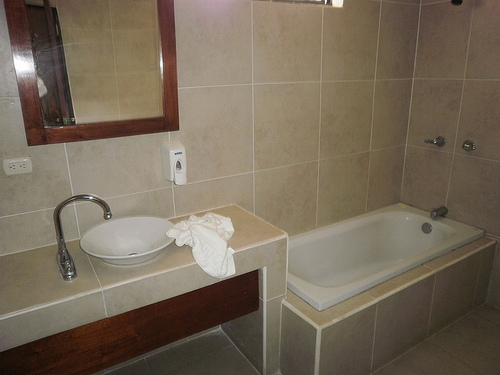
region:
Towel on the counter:
[165, 206, 235, 300]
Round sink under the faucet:
[77, 202, 194, 284]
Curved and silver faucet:
[42, 170, 129, 301]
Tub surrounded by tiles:
[327, 310, 378, 372]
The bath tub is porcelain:
[274, 188, 499, 337]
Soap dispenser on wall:
[160, 144, 200, 191]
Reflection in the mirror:
[27, 16, 174, 126]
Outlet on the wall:
[0, 148, 42, 195]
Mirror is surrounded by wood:
[145, 40, 210, 142]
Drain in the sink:
[122, 245, 139, 259]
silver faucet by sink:
[50, 186, 111, 278]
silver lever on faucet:
[61, 262, 73, 279]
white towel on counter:
[172, 205, 236, 265]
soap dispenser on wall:
[158, 142, 192, 187]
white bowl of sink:
[87, 205, 177, 265]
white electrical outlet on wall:
[0, 157, 32, 179]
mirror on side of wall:
[41, 0, 165, 117]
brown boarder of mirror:
[160, 0, 188, 131]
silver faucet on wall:
[426, 203, 454, 216]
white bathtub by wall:
[275, 206, 457, 303]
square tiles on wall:
[0, 5, 492, 242]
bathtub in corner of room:
[262, 194, 492, 371]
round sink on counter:
[78, 213, 175, 266]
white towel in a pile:
[169, 210, 237, 278]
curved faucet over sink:
[52, 192, 112, 281]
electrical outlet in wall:
[0, 155, 32, 176]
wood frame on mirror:
[7, 0, 179, 148]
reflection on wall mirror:
[28, 2, 167, 127]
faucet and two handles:
[421, 133, 475, 220]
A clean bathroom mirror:
[5, 13, 215, 124]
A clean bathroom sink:
[76, 212, 173, 253]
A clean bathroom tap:
[31, 180, 104, 301]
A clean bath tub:
[285, 199, 479, 289]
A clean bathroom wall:
[197, 76, 324, 160]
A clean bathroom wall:
[315, 77, 407, 180]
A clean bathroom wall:
[183, 12, 303, 67]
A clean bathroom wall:
[347, 9, 448, 66]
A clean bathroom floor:
[436, 326, 493, 371]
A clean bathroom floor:
[179, 348, 249, 373]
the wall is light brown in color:
[263, 79, 368, 182]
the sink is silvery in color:
[41, 190, 110, 256]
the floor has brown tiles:
[407, 300, 474, 370]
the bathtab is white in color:
[308, 199, 476, 257]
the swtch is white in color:
[163, 138, 208, 193]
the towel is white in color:
[183, 210, 231, 270]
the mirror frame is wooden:
[157, 35, 182, 131]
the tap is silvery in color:
[428, 124, 467, 159]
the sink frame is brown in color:
[108, 312, 231, 347]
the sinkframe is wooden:
[122, 293, 210, 354]